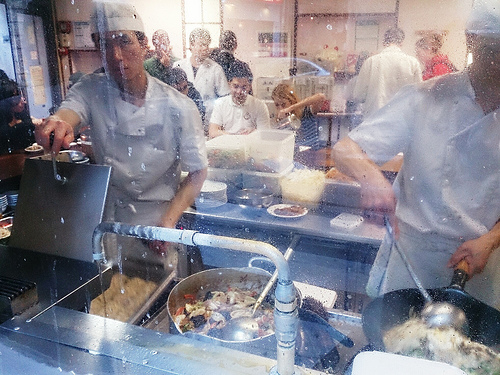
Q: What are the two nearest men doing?
A: Cooking.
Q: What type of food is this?
A: Asian.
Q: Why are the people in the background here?
A: To eat.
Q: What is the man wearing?
A: Uniform.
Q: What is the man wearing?
A: Dress.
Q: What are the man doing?
A: Serving.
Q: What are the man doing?
A: Working.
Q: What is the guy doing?
A: Stirring.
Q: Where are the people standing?
A: Resturant.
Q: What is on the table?
A: Food items.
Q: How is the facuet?
A: Grey.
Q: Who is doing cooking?
A: The men.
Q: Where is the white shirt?
A: On man.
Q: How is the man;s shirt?
A: White.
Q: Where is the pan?
A: On cooker.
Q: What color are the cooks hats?
A: White.